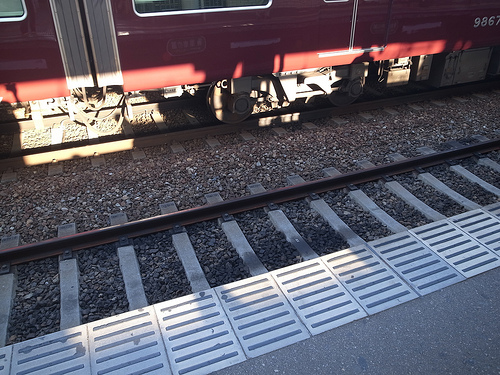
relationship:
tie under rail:
[56, 220, 81, 330] [0, 137, 499, 271]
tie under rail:
[109, 208, 149, 311] [0, 137, 499, 271]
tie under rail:
[158, 202, 209, 294] [0, 137, 499, 271]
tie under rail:
[204, 191, 268, 277] [0, 137, 499, 271]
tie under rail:
[246, 181, 319, 262] [0, 137, 499, 271]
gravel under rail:
[1, 105, 499, 347] [0, 137, 499, 271]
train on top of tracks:
[0, 0, 498, 126] [0, 93, 500, 172]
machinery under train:
[206, 50, 500, 126] [0, 0, 498, 126]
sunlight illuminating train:
[0, 40, 481, 166] [0, 0, 498, 126]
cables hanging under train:
[68, 87, 136, 137] [0, 0, 498, 126]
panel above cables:
[49, 1, 94, 90] [68, 87, 136, 137]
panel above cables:
[80, 1, 125, 89] [68, 87, 136, 137]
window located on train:
[133, 1, 271, 15] [0, 0, 498, 126]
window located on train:
[0, 0, 25, 18] [0, 0, 498, 126]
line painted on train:
[319, 0, 384, 57] [0, 0, 498, 126]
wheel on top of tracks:
[204, 80, 255, 125] [0, 93, 500, 172]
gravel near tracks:
[1, 105, 499, 347] [0, 93, 500, 172]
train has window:
[0, 0, 498, 126] [133, 1, 271, 15]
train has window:
[0, 0, 498, 126] [0, 0, 25, 18]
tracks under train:
[0, 93, 500, 172] [0, 0, 498, 126]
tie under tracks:
[46, 119, 64, 175] [0, 93, 500, 172]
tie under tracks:
[86, 119, 106, 168] [0, 93, 500, 172]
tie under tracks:
[122, 120, 147, 162] [0, 93, 500, 172]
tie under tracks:
[149, 112, 185, 155] [0, 93, 500, 172]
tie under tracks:
[184, 108, 222, 148] [0, 93, 500, 172]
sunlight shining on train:
[0, 40, 481, 166] [0, 0, 498, 126]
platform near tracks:
[0, 202, 498, 374] [0, 93, 500, 172]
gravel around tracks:
[1, 105, 499, 347] [0, 93, 500, 172]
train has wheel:
[0, 0, 498, 126] [204, 80, 255, 125]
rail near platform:
[0, 137, 499, 271] [0, 202, 498, 374]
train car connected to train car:
[81, 2, 499, 126] [0, 1, 94, 106]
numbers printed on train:
[470, 16, 499, 28] [0, 0, 498, 126]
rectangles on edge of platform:
[5, 200, 499, 371] [0, 202, 498, 374]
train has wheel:
[0, 0, 498, 126] [327, 81, 361, 105]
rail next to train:
[0, 137, 499, 271] [0, 0, 498, 126]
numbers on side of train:
[470, 16, 499, 28] [0, 0, 498, 126]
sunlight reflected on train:
[0, 40, 481, 166] [0, 0, 498, 126]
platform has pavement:
[0, 202, 498, 374] [210, 265, 499, 374]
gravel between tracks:
[1, 105, 499, 347] [0, 93, 500, 172]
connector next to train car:
[51, 0, 124, 91] [81, 2, 499, 126]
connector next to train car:
[51, 0, 124, 91] [0, 1, 94, 106]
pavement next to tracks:
[210, 265, 499, 374] [0, 93, 500, 172]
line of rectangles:
[2, 130, 499, 313] [5, 200, 499, 371]